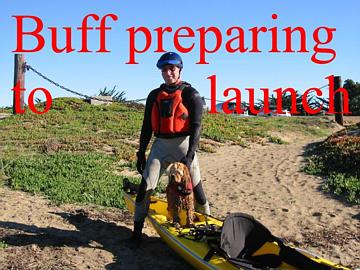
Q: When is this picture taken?
A: Daytime.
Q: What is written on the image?
A: Buff preparing to launch.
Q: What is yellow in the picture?
A: Kayak.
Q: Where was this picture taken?
A: On the shore.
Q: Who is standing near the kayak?
A: A man.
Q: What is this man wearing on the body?
A: Life jacket.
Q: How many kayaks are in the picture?
A: One.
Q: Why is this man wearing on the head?
A: Hat.